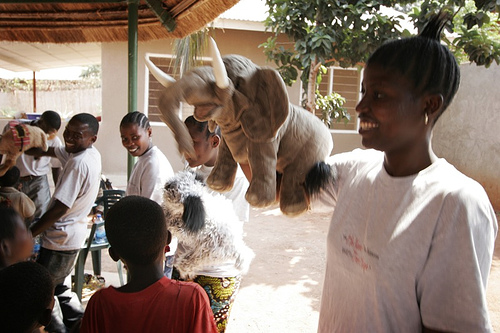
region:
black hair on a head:
[366, 31, 466, 86]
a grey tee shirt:
[293, 171, 463, 321]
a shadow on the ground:
[225, 208, 328, 316]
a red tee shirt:
[66, 277, 254, 332]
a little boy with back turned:
[66, 181, 236, 331]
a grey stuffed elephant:
[128, 51, 337, 225]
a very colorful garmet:
[178, 270, 235, 330]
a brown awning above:
[1, 4, 245, 46]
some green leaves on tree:
[256, 1, 497, 54]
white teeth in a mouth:
[346, 109, 389, 136]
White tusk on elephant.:
[195, 41, 242, 124]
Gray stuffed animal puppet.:
[158, 90, 295, 193]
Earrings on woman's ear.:
[418, 105, 443, 154]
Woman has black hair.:
[394, 38, 449, 82]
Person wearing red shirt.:
[107, 286, 194, 328]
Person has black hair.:
[120, 106, 165, 153]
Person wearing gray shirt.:
[127, 157, 168, 204]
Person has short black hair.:
[72, 100, 107, 167]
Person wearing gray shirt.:
[34, 175, 106, 285]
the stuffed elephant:
[143, 36, 335, 216]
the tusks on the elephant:
[145, 37, 229, 87]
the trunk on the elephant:
[155, 68, 200, 158]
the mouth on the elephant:
[187, 96, 222, 123]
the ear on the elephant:
[239, 64, 290, 143]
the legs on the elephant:
[206, 133, 313, 215]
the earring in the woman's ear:
[424, 113, 429, 125]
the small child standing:
[80, 194, 219, 331]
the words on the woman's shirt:
[342, 231, 379, 273]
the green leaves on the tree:
[256, 1, 498, 134]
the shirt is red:
[92, 276, 217, 331]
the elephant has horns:
[141, 41, 341, 197]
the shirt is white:
[321, 155, 496, 330]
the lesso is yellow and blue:
[205, 275, 250, 330]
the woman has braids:
[116, 105, 166, 177]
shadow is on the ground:
[257, 216, 299, 282]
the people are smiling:
[25, 100, 180, 197]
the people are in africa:
[0, 0, 475, 322]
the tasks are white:
[136, 39, 228, 103]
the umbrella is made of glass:
[6, 2, 210, 46]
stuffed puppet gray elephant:
[157, 37, 336, 222]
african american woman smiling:
[333, 33, 470, 329]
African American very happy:
[108, 103, 171, 214]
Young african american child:
[81, 192, 196, 329]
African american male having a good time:
[0, 108, 102, 300]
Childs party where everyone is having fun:
[1, 105, 206, 331]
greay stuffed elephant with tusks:
[133, 33, 340, 217]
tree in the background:
[261, 1, 358, 86]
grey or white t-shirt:
[323, 160, 487, 331]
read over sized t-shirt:
[76, 280, 221, 331]